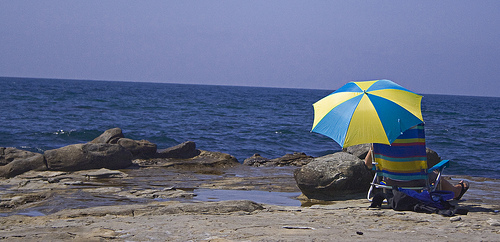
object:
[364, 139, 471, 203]
man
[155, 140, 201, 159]
stones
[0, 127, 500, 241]
shore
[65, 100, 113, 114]
waves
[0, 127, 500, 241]
rocky area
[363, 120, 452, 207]
chair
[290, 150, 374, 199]
boulder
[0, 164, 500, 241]
ground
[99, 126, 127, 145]
rock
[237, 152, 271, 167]
rock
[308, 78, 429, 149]
umbrella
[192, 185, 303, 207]
water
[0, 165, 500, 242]
sand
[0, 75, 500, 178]
ocean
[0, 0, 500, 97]
sky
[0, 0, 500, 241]
background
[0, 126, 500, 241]
beach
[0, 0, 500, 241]
scene